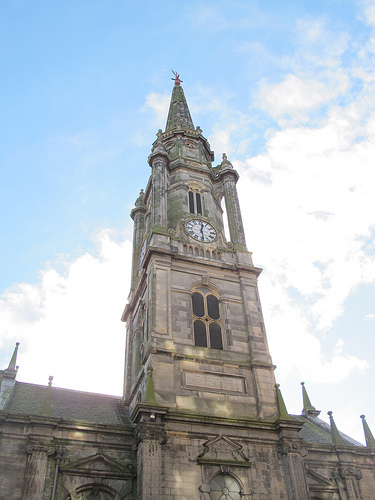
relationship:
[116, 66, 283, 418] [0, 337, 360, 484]
tower on a building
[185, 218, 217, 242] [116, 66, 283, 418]
clock in front of tower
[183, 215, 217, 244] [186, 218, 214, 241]
clock has roman numerals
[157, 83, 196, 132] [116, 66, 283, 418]
roof of tower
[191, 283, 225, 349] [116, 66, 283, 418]
window in front of tower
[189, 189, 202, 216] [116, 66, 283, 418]
window in front of tower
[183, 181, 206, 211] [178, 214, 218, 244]
window over clock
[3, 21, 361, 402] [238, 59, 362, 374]
sky with white clouds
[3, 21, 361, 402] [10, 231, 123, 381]
sky with white clouds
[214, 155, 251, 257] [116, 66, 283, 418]
column on right side of tower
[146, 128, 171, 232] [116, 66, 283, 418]
column on side of tower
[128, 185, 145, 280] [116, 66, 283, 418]
column on side of tower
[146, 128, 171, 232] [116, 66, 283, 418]
column on left side of tower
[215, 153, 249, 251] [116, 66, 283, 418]
column on side of tower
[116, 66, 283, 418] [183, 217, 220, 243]
tower has a clock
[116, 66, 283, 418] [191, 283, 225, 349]
tower has window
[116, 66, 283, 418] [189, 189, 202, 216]
tower has window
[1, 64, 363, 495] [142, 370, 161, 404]
building has moss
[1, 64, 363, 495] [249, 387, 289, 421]
building has moss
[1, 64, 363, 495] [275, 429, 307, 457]
building has many details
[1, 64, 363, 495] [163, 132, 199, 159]
building has many details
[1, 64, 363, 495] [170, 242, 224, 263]
building has many details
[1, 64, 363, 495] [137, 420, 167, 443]
building has many details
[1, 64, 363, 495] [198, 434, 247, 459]
building has many details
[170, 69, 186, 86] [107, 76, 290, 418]
statue on top of tower